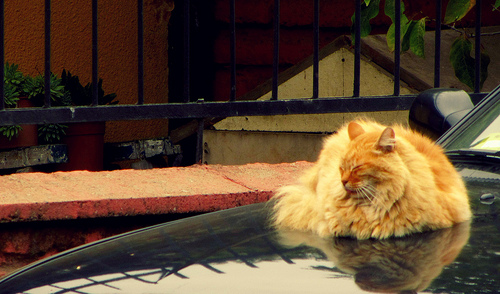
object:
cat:
[275, 117, 474, 239]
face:
[339, 145, 378, 200]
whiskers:
[353, 179, 384, 206]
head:
[338, 122, 411, 199]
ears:
[346, 117, 398, 152]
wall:
[0, 210, 183, 270]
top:
[1, 160, 318, 222]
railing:
[1, 1, 499, 127]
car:
[0, 82, 500, 293]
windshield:
[432, 85, 499, 163]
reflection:
[301, 224, 473, 293]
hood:
[1, 183, 500, 293]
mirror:
[410, 87, 475, 137]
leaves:
[0, 61, 120, 145]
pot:
[45, 117, 108, 171]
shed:
[171, 1, 494, 161]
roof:
[332, 25, 498, 93]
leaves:
[350, 1, 486, 94]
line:
[60, 234, 63, 242]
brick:
[34, 221, 106, 254]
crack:
[50, 231, 62, 250]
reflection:
[44, 257, 351, 293]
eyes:
[336, 162, 368, 174]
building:
[4, 2, 486, 171]